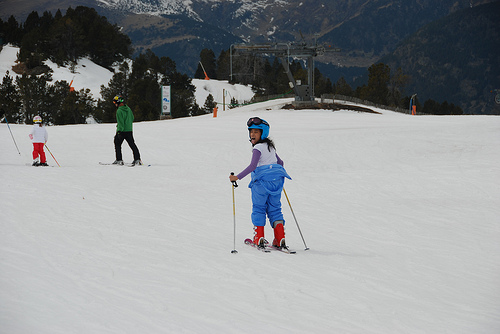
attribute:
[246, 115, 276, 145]
head gear — blue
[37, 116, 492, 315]
field — snowy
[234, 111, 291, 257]
female — young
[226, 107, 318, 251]
skier — young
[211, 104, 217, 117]
pole — orange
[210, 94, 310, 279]
girl — young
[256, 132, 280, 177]
vest — white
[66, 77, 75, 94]
flag — orange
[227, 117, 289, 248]
person — looking back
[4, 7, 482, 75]
mountain — side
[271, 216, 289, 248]
shoe — red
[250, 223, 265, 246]
shoe — red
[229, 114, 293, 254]
skier — young